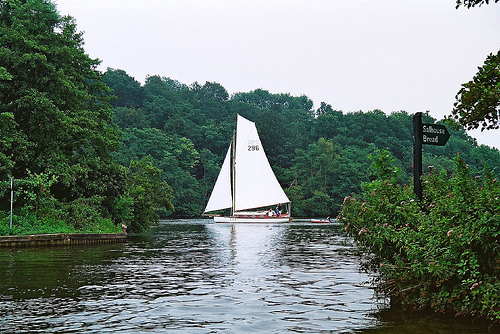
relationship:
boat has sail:
[200, 115, 292, 222] [236, 110, 290, 210]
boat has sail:
[200, 115, 292, 222] [203, 135, 234, 217]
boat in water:
[200, 115, 292, 222] [2, 218, 500, 332]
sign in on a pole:
[421, 112, 451, 148] [413, 110, 424, 200]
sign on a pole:
[421, 112, 451, 148] [413, 110, 424, 200]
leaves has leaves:
[0, 0, 119, 187] [1, 2, 130, 200]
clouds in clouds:
[54, 1, 500, 151] [49, 0, 500, 151]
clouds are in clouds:
[54, 1, 500, 151] [49, 0, 500, 151]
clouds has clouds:
[49, 0, 500, 151] [54, 1, 500, 151]